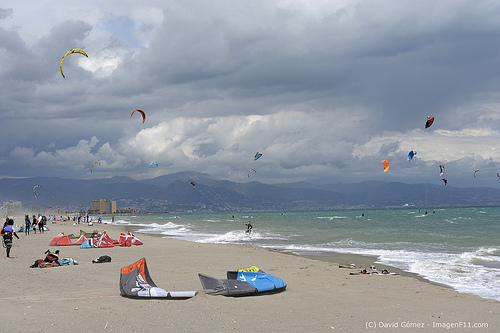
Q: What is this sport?
A: Sail surfing.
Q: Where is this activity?
A: On the seashore.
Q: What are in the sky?
A: Many sails.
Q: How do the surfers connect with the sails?
A: Using tow ropes.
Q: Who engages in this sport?
A: Expert surfers.